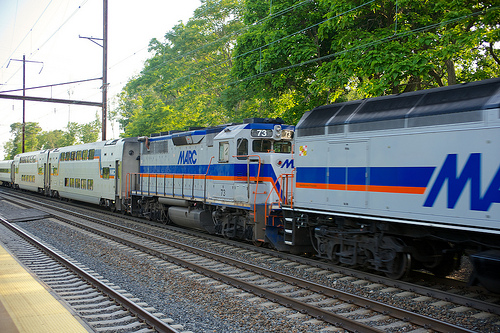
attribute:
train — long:
[4, 65, 495, 280]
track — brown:
[337, 254, 483, 308]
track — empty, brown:
[15, 211, 212, 321]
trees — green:
[111, 3, 490, 129]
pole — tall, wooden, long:
[74, 5, 115, 141]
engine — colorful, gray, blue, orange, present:
[127, 111, 288, 248]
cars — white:
[12, 137, 140, 212]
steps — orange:
[256, 171, 302, 253]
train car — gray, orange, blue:
[288, 78, 495, 279]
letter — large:
[423, 147, 481, 218]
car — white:
[12, 150, 47, 199]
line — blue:
[287, 161, 438, 186]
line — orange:
[296, 182, 428, 198]